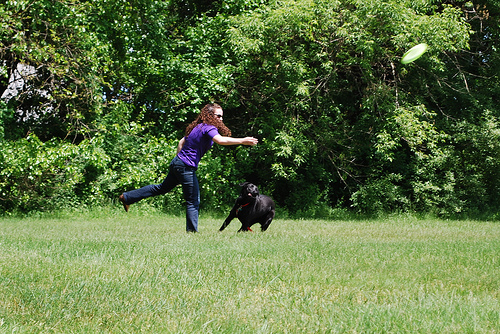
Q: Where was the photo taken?
A: It was taken at the field.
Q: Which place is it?
A: It is a field.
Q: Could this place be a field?
A: Yes, it is a field.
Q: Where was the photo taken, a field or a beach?
A: It was taken at a field.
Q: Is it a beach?
A: No, it is a field.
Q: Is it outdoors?
A: Yes, it is outdoors.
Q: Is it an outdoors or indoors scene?
A: It is outdoors.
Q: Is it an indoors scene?
A: No, it is outdoors.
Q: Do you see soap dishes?
A: No, there are no soap dishes.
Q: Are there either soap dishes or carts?
A: No, there are no soap dishes or carts.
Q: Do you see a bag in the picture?
A: No, there are no bags.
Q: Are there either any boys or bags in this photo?
A: No, there are no bags or boys.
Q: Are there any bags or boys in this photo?
A: No, there are no bags or boys.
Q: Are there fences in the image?
A: No, there are no fences.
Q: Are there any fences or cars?
A: No, there are no fences or cars.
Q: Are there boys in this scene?
A: No, there are no boys.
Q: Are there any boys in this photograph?
A: No, there are no boys.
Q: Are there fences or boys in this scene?
A: No, there are no boys or fences.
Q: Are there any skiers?
A: No, there are no skiers.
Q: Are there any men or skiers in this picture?
A: No, there are no skiers or men.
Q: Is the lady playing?
A: Yes, the lady is playing.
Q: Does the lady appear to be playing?
A: Yes, the lady is playing.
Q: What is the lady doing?
A: The lady is playing.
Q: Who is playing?
A: The lady is playing.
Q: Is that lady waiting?
A: No, the lady is playing.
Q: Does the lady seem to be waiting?
A: No, the lady is playing.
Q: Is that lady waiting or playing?
A: The lady is playing.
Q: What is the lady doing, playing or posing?
A: The lady is playing.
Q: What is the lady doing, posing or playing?
A: The lady is playing.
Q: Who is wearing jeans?
A: The lady is wearing jeans.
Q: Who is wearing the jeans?
A: The lady is wearing jeans.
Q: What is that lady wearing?
A: The lady is wearing jeans.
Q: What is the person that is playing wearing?
A: The lady is wearing jeans.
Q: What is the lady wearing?
A: The lady is wearing jeans.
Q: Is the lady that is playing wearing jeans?
A: Yes, the lady is wearing jeans.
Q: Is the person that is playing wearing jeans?
A: Yes, the lady is wearing jeans.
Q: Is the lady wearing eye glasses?
A: No, the lady is wearing jeans.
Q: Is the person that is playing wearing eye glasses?
A: No, the lady is wearing jeans.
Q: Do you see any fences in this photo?
A: No, there are no fences.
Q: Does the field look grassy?
A: Yes, the field is grassy.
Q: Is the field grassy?
A: Yes, the field is grassy.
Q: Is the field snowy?
A: No, the field is grassy.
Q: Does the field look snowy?
A: No, the field is grassy.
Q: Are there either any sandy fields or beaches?
A: No, there is a field but it is grassy.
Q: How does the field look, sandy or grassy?
A: The field is grassy.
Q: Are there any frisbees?
A: Yes, there is a frisbee.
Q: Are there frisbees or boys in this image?
A: Yes, there is a frisbee.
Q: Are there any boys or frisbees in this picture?
A: Yes, there is a frisbee.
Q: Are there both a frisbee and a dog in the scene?
A: Yes, there are both a frisbee and a dog.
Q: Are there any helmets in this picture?
A: No, there are no helmets.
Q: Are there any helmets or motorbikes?
A: No, there are no helmets or motorbikes.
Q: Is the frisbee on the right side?
A: Yes, the frisbee is on the right of the image.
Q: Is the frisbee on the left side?
A: No, the frisbee is on the right of the image.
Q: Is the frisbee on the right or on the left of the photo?
A: The frisbee is on the right of the image.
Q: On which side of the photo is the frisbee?
A: The frisbee is on the right of the image.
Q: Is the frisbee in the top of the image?
A: Yes, the frisbee is in the top of the image.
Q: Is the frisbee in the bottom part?
A: No, the frisbee is in the top of the image.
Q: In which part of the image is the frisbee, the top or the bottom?
A: The frisbee is in the top of the image.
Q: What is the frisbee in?
A: The frisbee is in the air.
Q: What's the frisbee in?
A: The frisbee is in the air.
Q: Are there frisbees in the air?
A: Yes, there is a frisbee in the air.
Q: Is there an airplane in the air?
A: No, there is a frisbee in the air.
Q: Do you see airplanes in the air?
A: No, there is a frisbee in the air.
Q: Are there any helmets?
A: No, there are no helmets.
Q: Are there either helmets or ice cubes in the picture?
A: No, there are no helmets or ice cubes.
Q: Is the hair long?
A: Yes, the hair is long.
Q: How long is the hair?
A: The hair is long.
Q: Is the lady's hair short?
A: No, the hair is long.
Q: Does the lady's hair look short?
A: No, the hair is long.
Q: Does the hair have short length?
A: No, the hair is long.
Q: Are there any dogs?
A: Yes, there is a dog.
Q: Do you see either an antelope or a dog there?
A: Yes, there is a dog.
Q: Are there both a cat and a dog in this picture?
A: No, there is a dog but no cats.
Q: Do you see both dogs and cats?
A: No, there is a dog but no cats.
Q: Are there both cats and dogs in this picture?
A: No, there is a dog but no cats.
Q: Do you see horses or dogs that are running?
A: Yes, the dog is running.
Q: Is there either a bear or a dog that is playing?
A: Yes, the dog is playing.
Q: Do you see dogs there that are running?
A: Yes, there is a dog that is running.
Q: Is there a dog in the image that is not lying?
A: Yes, there is a dog that is running.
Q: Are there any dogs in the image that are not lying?
A: Yes, there is a dog that is running.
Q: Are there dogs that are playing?
A: Yes, there is a dog that is playing.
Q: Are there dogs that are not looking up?
A: Yes, there is a dog that is playing.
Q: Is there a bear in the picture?
A: No, there are no bears.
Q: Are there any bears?
A: No, there are no bears.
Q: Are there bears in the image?
A: No, there are no bears.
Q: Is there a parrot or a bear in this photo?
A: No, there are no bears or parrots.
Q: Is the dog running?
A: Yes, the dog is running.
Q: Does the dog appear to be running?
A: Yes, the dog is running.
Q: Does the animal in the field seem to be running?
A: Yes, the dog is running.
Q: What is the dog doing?
A: The dog is running.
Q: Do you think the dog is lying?
A: No, the dog is running.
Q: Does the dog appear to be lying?
A: No, the dog is running.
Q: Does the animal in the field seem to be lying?
A: No, the dog is running.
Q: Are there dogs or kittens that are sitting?
A: No, there is a dog but it is running.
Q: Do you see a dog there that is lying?
A: No, there is a dog but it is running.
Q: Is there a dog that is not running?
A: No, there is a dog but it is running.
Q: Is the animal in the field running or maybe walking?
A: The dog is running.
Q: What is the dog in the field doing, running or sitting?
A: The dog is running.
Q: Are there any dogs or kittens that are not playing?
A: No, there is a dog but it is playing.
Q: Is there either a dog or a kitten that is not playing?
A: No, there is a dog but it is playing.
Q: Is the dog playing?
A: Yes, the dog is playing.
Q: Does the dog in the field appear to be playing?
A: Yes, the dog is playing.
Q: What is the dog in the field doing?
A: The dog is playing.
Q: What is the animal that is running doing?
A: The dog is playing.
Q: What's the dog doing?
A: The dog is playing.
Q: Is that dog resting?
A: No, the dog is playing.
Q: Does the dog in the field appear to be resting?
A: No, the dog is playing.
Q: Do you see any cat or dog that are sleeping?
A: No, there is a dog but it is playing.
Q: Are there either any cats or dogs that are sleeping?
A: No, there is a dog but it is playing.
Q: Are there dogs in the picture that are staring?
A: No, there is a dog but it is playing.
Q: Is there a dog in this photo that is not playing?
A: No, there is a dog but it is playing.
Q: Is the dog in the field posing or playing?
A: The dog is playing.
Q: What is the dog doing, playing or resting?
A: The dog is playing.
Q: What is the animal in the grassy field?
A: The animal is a dog.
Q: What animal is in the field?
A: The animal is a dog.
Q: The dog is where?
A: The dog is in the field.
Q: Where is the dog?
A: The dog is in the field.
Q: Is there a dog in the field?
A: Yes, there is a dog in the field.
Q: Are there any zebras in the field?
A: No, there is a dog in the field.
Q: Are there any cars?
A: No, there are no cars.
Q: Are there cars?
A: No, there are no cars.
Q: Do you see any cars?
A: No, there are no cars.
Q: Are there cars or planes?
A: No, there are no cars or planes.